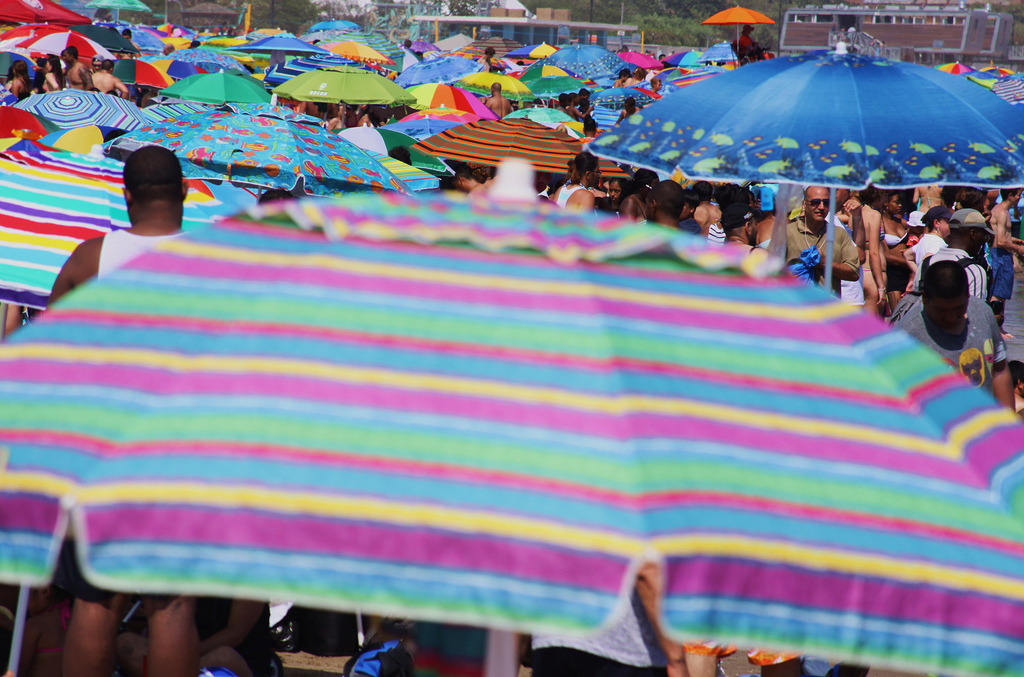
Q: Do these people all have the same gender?
A: No, they are both male and female.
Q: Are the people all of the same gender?
A: No, they are both male and female.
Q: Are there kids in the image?
A: No, there are no kids.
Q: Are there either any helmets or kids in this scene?
A: No, there are no kids or helmets.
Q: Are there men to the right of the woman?
A: Yes, there is a man to the right of the woman.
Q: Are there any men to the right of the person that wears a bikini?
A: Yes, there is a man to the right of the woman.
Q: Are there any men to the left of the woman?
A: No, the man is to the right of the woman.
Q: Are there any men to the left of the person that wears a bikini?
A: No, the man is to the right of the woman.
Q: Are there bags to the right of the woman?
A: No, there is a man to the right of the woman.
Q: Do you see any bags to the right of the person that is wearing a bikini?
A: No, there is a man to the right of the woman.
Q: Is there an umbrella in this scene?
A: Yes, there is an umbrella.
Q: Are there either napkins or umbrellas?
A: Yes, there is an umbrella.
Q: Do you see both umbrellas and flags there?
A: No, there is an umbrella but no flags.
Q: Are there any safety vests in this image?
A: No, there are no safety vests.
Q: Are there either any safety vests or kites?
A: No, there are no safety vests or kites.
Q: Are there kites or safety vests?
A: No, there are no safety vests or kites.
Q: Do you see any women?
A: Yes, there is a woman.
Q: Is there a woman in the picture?
A: Yes, there is a woman.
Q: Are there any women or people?
A: Yes, there is a woman.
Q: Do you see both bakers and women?
A: No, there is a woman but no bakers.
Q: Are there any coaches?
A: No, there are no coaches.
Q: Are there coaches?
A: No, there are no coaches.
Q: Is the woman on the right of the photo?
A: Yes, the woman is on the right of the image.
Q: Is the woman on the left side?
A: No, the woman is on the right of the image.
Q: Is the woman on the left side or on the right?
A: The woman is on the right of the image.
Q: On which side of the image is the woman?
A: The woman is on the right of the image.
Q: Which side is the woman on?
A: The woman is on the right of the image.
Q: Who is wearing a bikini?
A: The woman is wearing a bikini.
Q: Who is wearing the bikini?
A: The woman is wearing a bikini.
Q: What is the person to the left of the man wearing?
A: The woman is wearing a bikini.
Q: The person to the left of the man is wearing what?
A: The woman is wearing a bikini.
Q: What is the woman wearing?
A: The woman is wearing a bikini.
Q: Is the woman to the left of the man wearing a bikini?
A: Yes, the woman is wearing a bikini.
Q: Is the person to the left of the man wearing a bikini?
A: Yes, the woman is wearing a bikini.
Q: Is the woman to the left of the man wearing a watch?
A: No, the woman is wearing a bikini.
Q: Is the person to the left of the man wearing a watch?
A: No, the woman is wearing a bikini.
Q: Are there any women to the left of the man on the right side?
A: Yes, there is a woman to the left of the man.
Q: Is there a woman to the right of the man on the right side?
A: No, the woman is to the left of the man.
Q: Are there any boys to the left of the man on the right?
A: No, there is a woman to the left of the man.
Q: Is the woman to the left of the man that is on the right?
A: Yes, the woman is to the left of the man.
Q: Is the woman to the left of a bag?
A: No, the woman is to the left of the man.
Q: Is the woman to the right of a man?
A: No, the woman is to the left of a man.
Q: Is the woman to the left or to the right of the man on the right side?
A: The woman is to the left of the man.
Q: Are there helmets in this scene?
A: No, there are no helmets.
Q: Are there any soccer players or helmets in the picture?
A: No, there are no helmets or soccer players.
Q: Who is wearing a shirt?
A: The man is wearing a shirt.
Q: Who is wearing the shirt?
A: The man is wearing a shirt.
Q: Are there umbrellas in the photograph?
A: Yes, there is an umbrella.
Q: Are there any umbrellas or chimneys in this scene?
A: Yes, there is an umbrella.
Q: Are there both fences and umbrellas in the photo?
A: No, there is an umbrella but no fences.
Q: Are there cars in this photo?
A: No, there are no cars.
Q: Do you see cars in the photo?
A: No, there are no cars.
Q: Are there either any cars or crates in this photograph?
A: No, there are no cars or crates.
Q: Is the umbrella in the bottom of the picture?
A: No, the umbrella is in the top of the image.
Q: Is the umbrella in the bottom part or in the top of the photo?
A: The umbrella is in the top of the image.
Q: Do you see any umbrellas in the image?
A: Yes, there is an umbrella.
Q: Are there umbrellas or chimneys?
A: Yes, there is an umbrella.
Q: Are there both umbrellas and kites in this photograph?
A: No, there is an umbrella but no kites.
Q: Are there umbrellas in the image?
A: Yes, there is an umbrella.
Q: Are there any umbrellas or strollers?
A: Yes, there is an umbrella.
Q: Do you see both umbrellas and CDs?
A: No, there is an umbrella but no cds.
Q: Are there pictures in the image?
A: No, there are no pictures.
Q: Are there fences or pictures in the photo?
A: No, there are no pictures or fences.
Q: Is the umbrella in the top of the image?
A: Yes, the umbrella is in the top of the image.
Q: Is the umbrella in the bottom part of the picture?
A: No, the umbrella is in the top of the image.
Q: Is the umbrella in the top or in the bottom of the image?
A: The umbrella is in the top of the image.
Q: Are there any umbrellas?
A: Yes, there is an umbrella.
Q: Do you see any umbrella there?
A: Yes, there is an umbrella.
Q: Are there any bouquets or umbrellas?
A: Yes, there is an umbrella.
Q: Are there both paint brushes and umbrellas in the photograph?
A: No, there is an umbrella but no paint brushes.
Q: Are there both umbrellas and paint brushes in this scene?
A: No, there is an umbrella but no paint brushes.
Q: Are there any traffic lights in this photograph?
A: No, there are no traffic lights.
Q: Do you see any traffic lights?
A: No, there are no traffic lights.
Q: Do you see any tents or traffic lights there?
A: No, there are no traffic lights or tents.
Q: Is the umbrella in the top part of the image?
A: Yes, the umbrella is in the top of the image.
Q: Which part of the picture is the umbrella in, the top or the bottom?
A: The umbrella is in the top of the image.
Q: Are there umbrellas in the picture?
A: Yes, there is an umbrella.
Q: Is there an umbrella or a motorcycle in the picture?
A: Yes, there is an umbrella.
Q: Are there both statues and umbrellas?
A: No, there is an umbrella but no statues.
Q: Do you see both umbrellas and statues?
A: No, there is an umbrella but no statues.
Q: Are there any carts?
A: No, there are no carts.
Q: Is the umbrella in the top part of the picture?
A: Yes, the umbrella is in the top of the image.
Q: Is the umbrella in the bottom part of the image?
A: No, the umbrella is in the top of the image.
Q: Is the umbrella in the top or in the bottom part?
A: The umbrella is in the top of the image.